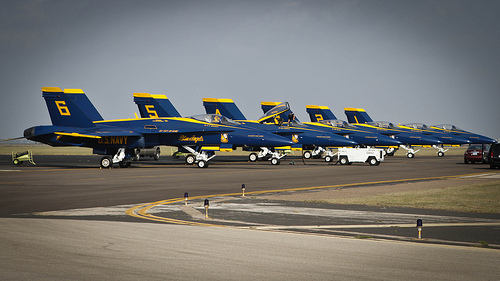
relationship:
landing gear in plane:
[429, 142, 451, 157] [408, 117, 475, 159]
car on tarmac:
[326, 144, 395, 185] [5, 160, 497, 209]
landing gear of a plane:
[178, 151, 214, 165] [17, 58, 312, 174]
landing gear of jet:
[401, 145, 426, 162] [23, 86, 303, 169]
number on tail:
[52, 100, 72, 116] [42, 89, 101, 127]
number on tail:
[52, 100, 72, 118] [40, 87, 109, 128]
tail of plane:
[40, 87, 109, 128] [25, 102, 289, 164]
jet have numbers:
[23, 86, 303, 169] [50, 100, 70, 118]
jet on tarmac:
[23, 86, 303, 169] [8, 144, 497, 239]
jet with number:
[17, 81, 302, 162] [52, 100, 72, 116]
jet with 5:
[26, 81, 248, 173] [144, 102, 159, 122]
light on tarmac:
[405, 210, 427, 240] [30, 166, 177, 181]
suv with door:
[484, 139, 496, 167] [483, 144, 491, 160]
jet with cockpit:
[203, 99, 368, 161] [254, 102, 306, 127]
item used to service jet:
[10, 149, 36, 165] [22, 84, 293, 168]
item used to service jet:
[10, 149, 36, 165] [133, 92, 355, 166]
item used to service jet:
[10, 149, 36, 165] [203, 99, 368, 161]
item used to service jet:
[10, 149, 36, 165] [260, 101, 401, 164]